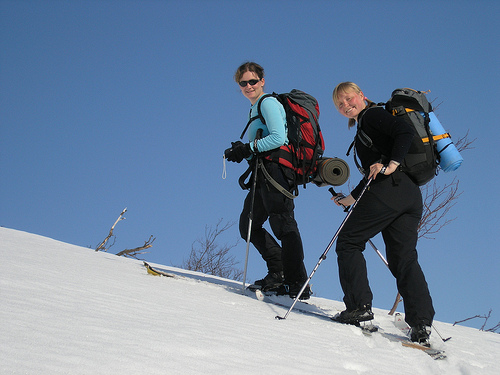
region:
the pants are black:
[336, 199, 441, 321]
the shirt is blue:
[237, 97, 289, 153]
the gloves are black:
[221, 136, 260, 165]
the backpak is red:
[283, 85, 339, 174]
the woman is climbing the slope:
[337, 84, 467, 340]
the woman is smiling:
[336, 78, 454, 345]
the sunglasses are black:
[224, 62, 331, 298]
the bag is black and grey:
[384, 85, 441, 186]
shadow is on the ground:
[156, 263, 228, 293]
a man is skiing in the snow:
[151, 47, 491, 370]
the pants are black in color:
[335, 177, 440, 332]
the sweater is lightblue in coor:
[232, 102, 305, 142]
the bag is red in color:
[294, 96, 335, 242]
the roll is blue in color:
[410, 98, 460, 188]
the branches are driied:
[122, 212, 253, 288]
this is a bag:
[390, 90, 444, 176]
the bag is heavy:
[393, 86, 445, 168]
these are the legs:
[338, 225, 410, 331]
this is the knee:
[337, 226, 369, 253]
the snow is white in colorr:
[60, 280, 165, 372]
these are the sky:
[7, 8, 210, 142]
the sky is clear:
[63, 37, 155, 132]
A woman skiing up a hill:
[140, 60, 350, 314]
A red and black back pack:
[238, 88, 350, 200]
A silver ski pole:
[272, 163, 387, 319]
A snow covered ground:
[1, 226, 498, 374]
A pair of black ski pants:
[337, 170, 435, 326]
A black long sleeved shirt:
[351, 101, 414, 198]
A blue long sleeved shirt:
[247, 92, 289, 155]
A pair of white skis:
[255, 288, 447, 358]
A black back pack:
[352, 86, 462, 185]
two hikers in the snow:
[145, 59, 462, 359]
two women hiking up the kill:
[143, 60, 463, 364]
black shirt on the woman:
[350, 104, 423, 205]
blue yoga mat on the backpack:
[424, 114, 462, 171]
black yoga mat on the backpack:
[312, 157, 351, 190]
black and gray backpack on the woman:
[384, 97, 436, 183]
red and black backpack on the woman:
[265, 89, 324, 188]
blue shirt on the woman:
[235, 95, 288, 170]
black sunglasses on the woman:
[237, 77, 260, 89]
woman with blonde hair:
[323, 81, 440, 360]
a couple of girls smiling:
[93, 64, 498, 301]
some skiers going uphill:
[123, 43, 475, 308]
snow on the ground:
[1, 220, 491, 372]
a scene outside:
[13, 14, 495, 358]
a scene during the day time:
[23, 27, 498, 315]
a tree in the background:
[174, 201, 343, 344]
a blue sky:
[6, 15, 490, 292]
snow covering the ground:
[71, 253, 163, 365]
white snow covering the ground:
[16, 266, 86, 359]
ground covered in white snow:
[16, 246, 88, 336]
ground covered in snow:
[50, 245, 162, 375]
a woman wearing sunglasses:
[214, 27, 345, 247]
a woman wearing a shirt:
[222, 42, 290, 202]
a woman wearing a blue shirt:
[235, 33, 321, 195]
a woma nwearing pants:
[225, 47, 300, 260]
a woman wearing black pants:
[254, 82, 298, 267]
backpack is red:
[247, 85, 328, 179]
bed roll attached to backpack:
[311, 147, 353, 192]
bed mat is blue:
[419, 96, 465, 173]